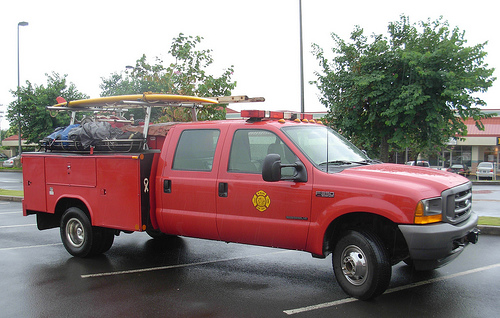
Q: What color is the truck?
A: Red.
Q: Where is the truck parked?
A: Parking lot.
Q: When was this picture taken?
A: Daytime.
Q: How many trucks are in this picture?
A: 1.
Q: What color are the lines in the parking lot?
A: White.